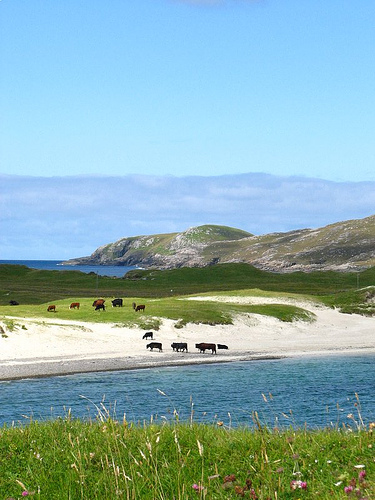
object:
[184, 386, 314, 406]
ripples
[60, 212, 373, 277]
mountains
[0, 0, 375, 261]
sky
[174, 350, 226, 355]
shadow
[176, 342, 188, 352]
animal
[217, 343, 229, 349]
animal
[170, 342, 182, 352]
animal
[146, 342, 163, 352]
animal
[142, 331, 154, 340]
animal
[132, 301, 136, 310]
animal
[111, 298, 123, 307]
animal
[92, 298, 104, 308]
animal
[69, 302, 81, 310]
animal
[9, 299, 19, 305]
cattle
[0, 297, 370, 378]
beaches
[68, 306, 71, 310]
head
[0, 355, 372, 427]
water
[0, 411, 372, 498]
grass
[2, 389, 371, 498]
plants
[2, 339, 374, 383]
shoreline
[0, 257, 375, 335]
grassland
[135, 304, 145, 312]
cow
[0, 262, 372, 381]
island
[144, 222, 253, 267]
hill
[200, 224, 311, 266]
hill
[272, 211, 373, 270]
hill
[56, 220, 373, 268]
island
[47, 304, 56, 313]
cow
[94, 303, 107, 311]
cow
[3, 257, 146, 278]
water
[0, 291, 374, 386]
sand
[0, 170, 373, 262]
cloud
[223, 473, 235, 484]
flower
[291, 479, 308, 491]
flower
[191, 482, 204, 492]
flower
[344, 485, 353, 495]
flower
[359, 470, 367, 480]
flower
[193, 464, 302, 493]
thistle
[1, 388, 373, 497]
hillside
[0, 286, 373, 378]
stand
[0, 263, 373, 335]
grass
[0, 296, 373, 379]
shore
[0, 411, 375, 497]
wild flowers